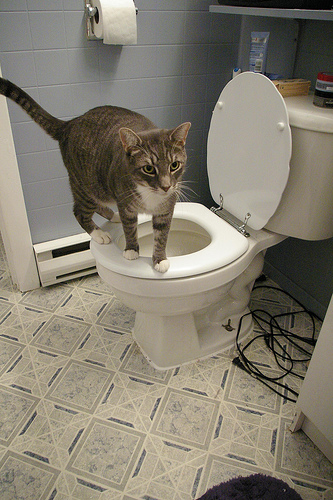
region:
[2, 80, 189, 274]
A gray and white cat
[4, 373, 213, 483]
The tile on a bathroom floor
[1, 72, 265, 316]
A cat standing on a toilet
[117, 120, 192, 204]
The face of a cat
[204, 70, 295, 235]
A white toilet lid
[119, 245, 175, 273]
Two white paws of a cat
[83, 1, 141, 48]
A roll of toilet paper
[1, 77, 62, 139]
A cat's tail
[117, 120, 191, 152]
Two ears of a cat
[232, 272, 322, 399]
A black cord on a floor by a toilet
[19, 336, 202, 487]
the floor is tiled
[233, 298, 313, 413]
wires on the floor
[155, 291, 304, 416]
wires behind the toilet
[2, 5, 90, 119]
the wall is tiled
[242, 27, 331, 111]
bottles on the toilet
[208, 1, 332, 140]
shelf is above toilet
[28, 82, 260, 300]
cat is on the toilet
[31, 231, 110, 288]
vent is on the wall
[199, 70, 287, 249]
toilet lid is up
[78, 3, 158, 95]
toilet paper on the wall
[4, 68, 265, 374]
tabby cat standing on a toilet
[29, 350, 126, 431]
blue white and grey bathroom floor tiles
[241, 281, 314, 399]
black electrical cord on a bathroom floor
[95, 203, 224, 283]
white toilet seat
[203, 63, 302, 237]
white lid of a toilet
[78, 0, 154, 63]
toilet paper on a silver holder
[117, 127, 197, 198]
head of a grey cat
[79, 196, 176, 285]
white paws of a cat on a toilet seat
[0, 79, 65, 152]
tail of a black and grey cat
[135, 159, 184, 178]
green eyes of a cat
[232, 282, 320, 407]
Electric cord on bathroom floor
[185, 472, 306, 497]
Area rug on bathroom floor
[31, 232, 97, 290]
Heating register on bathroom floor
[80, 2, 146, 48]
Toilet tissue dispenser on bathroom wall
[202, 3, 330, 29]
Wooden shelf above toilet tank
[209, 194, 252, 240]
Metal toilet seat hinges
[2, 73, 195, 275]
Cat standing on bathroom toilet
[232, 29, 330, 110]
Toiletries on toilet tank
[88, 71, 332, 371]
White toilet in bathroom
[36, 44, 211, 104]
Square tiles on bathroom wall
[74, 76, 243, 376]
a cat standing on the western toilet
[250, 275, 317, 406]
some cable in the floor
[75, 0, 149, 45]
napkin roll hanging in the wall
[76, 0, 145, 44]
white color napkin hanging in the silver hanger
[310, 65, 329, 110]
creams kept in the flush tank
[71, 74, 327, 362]
white color western toilet and flush tank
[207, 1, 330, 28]
a rack in the toilet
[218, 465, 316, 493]
floor mat in the floor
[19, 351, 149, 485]
white and blue color floor tiles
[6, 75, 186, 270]
a cat focusing on the camera